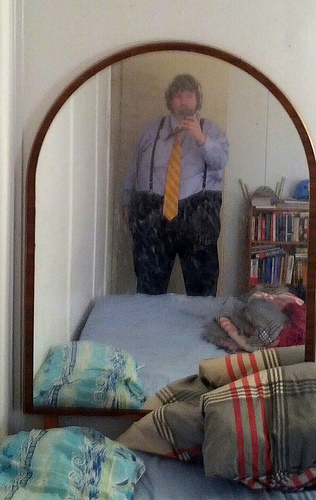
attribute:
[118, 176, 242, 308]
pants — black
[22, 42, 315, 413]
mirror — wooden, framed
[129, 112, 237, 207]
shirt — dress, blue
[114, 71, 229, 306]
man — large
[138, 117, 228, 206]
shirt — blue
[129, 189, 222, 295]
black pants — large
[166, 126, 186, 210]
tie — two tone, gold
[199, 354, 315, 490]
multi-tone comforter — gray, multi tone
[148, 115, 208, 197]
suspenders — black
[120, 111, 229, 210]
shirt — blue